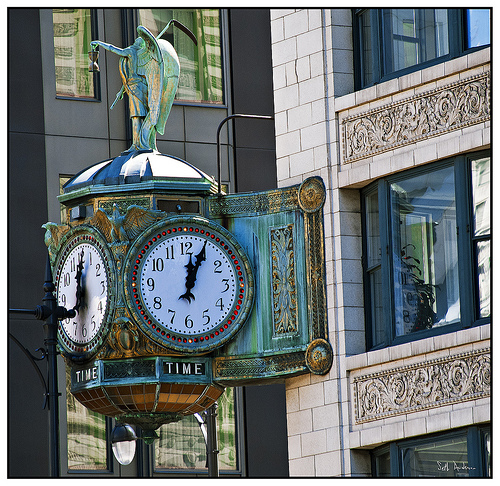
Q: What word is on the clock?
A: Time.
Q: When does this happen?
A: 12:05.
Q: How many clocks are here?
A: One.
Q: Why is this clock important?
A: To tell time.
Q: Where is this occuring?
A: On a city street.